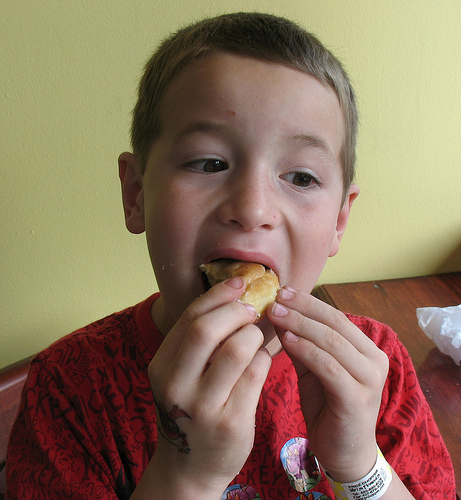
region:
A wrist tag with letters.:
[312, 452, 404, 496]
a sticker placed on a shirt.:
[275, 437, 321, 491]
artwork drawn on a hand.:
[149, 385, 201, 459]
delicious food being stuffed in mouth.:
[194, 239, 281, 331]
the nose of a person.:
[225, 163, 282, 246]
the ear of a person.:
[111, 145, 147, 235]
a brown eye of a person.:
[279, 159, 320, 202]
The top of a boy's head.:
[140, 0, 356, 121]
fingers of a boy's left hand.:
[275, 297, 382, 392]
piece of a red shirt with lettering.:
[20, 338, 155, 443]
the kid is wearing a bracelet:
[289, 344, 396, 492]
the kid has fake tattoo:
[133, 376, 219, 468]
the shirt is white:
[81, 316, 417, 495]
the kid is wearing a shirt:
[60, 325, 314, 493]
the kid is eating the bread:
[195, 246, 329, 386]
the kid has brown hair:
[166, 15, 360, 123]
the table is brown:
[337, 287, 458, 349]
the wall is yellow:
[22, 69, 111, 163]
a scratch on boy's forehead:
[220, 103, 243, 118]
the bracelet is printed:
[316, 460, 391, 498]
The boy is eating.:
[99, 57, 399, 429]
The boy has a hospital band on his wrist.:
[305, 461, 410, 498]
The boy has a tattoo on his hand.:
[133, 379, 202, 451]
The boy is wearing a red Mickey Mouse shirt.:
[36, 370, 175, 498]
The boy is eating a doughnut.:
[184, 247, 349, 333]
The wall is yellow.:
[17, 125, 84, 263]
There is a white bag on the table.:
[414, 287, 458, 371]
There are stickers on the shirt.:
[226, 450, 334, 498]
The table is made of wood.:
[379, 264, 458, 339]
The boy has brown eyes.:
[164, 138, 351, 197]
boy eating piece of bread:
[75, 24, 390, 486]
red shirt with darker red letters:
[20, 306, 445, 481]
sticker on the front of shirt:
[268, 428, 326, 489]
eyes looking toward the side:
[172, 134, 345, 220]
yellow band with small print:
[290, 446, 396, 492]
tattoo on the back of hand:
[122, 381, 228, 457]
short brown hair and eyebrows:
[104, 10, 370, 330]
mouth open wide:
[166, 236, 314, 322]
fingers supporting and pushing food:
[188, 247, 297, 331]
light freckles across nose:
[183, 182, 317, 229]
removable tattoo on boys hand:
[147, 377, 202, 456]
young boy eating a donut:
[84, 93, 457, 445]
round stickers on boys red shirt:
[225, 424, 370, 498]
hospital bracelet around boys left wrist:
[318, 421, 421, 498]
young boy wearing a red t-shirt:
[31, 21, 459, 497]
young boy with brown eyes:
[129, 90, 358, 362]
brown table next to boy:
[355, 275, 458, 489]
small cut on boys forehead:
[193, 93, 260, 140]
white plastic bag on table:
[415, 275, 460, 394]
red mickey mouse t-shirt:
[23, 341, 139, 486]